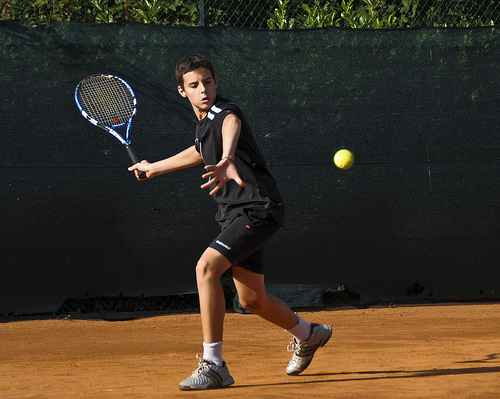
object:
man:
[126, 56, 331, 391]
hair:
[170, 55, 218, 90]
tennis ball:
[324, 145, 357, 171]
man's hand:
[123, 153, 160, 187]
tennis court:
[0, 301, 497, 399]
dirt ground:
[0, 304, 497, 399]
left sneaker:
[176, 355, 234, 387]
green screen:
[274, 51, 497, 132]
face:
[181, 66, 215, 109]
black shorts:
[210, 210, 297, 277]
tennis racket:
[68, 71, 151, 177]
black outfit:
[193, 98, 281, 276]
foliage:
[263, 0, 298, 27]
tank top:
[183, 100, 283, 210]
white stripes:
[207, 108, 216, 120]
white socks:
[201, 343, 225, 359]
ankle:
[198, 341, 220, 353]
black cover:
[1, 32, 499, 316]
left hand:
[198, 162, 244, 193]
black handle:
[116, 142, 147, 184]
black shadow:
[225, 353, 497, 385]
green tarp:
[0, 30, 499, 315]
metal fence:
[3, 2, 493, 313]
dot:
[108, 112, 121, 126]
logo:
[202, 364, 224, 382]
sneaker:
[177, 351, 239, 391]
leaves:
[2, 1, 15, 10]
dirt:
[0, 303, 499, 396]